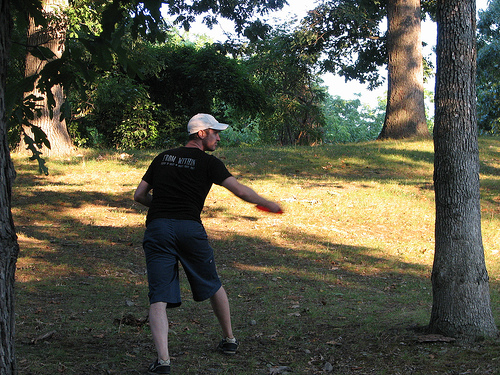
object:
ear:
[198, 129, 207, 139]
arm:
[208, 154, 263, 205]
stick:
[23, 328, 59, 348]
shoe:
[147, 356, 176, 375]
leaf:
[104, 87, 118, 106]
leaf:
[134, 128, 147, 140]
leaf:
[186, 63, 202, 83]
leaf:
[212, 76, 218, 85]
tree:
[80, 0, 266, 148]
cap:
[187, 113, 230, 137]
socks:
[221, 336, 237, 343]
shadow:
[0, 169, 500, 375]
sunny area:
[202, 173, 499, 280]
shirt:
[141, 146, 234, 223]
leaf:
[121, 51, 138, 64]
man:
[132, 112, 284, 375]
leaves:
[0, 137, 500, 375]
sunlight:
[40, 123, 79, 155]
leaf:
[149, 65, 170, 80]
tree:
[419, 0, 498, 344]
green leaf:
[0, 0, 500, 175]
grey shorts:
[143, 218, 224, 309]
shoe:
[216, 335, 239, 355]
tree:
[374, 0, 429, 140]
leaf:
[195, 39, 256, 94]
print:
[161, 154, 196, 170]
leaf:
[255, 50, 261, 56]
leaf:
[257, 55, 267, 61]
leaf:
[270, 48, 277, 53]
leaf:
[264, 85, 269, 89]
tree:
[245, 0, 331, 147]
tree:
[6, 0, 82, 164]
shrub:
[59, 0, 276, 154]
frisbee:
[255, 202, 284, 215]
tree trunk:
[419, 0, 500, 341]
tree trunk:
[371, 0, 430, 142]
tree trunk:
[0, 0, 80, 162]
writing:
[160, 154, 195, 170]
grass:
[0, 130, 500, 375]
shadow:
[375, 0, 435, 142]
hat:
[187, 112, 230, 136]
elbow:
[133, 190, 146, 203]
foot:
[147, 355, 174, 375]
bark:
[427, 0, 500, 342]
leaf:
[134, 130, 140, 137]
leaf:
[139, 105, 143, 111]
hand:
[261, 198, 280, 212]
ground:
[0, 132, 500, 375]